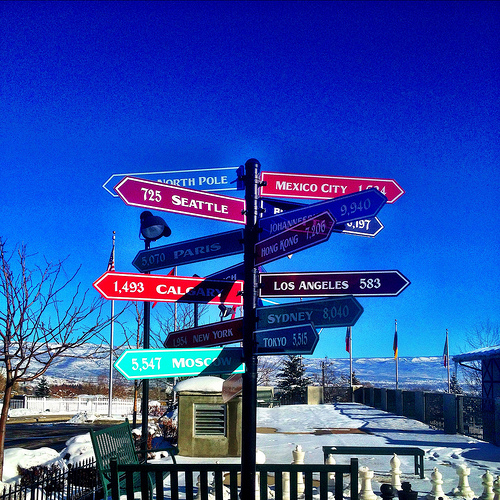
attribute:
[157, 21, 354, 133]
sky — blue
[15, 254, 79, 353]
tree — bare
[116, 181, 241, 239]
sign — red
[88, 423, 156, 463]
bench — green